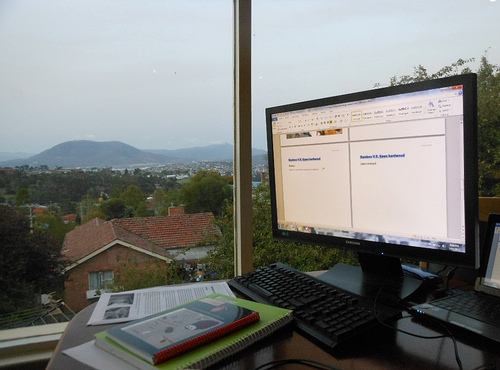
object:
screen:
[266, 74, 480, 270]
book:
[104, 295, 262, 366]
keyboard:
[226, 261, 397, 353]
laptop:
[408, 212, 499, 345]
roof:
[110, 209, 223, 250]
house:
[56, 220, 173, 312]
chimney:
[168, 202, 184, 216]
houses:
[107, 211, 224, 276]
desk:
[48, 272, 500, 369]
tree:
[197, 177, 225, 212]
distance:
[0, 136, 237, 217]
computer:
[261, 72, 484, 330]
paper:
[87, 279, 234, 326]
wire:
[373, 279, 451, 340]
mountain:
[31, 138, 161, 169]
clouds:
[166, 46, 218, 78]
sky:
[1, 0, 500, 157]